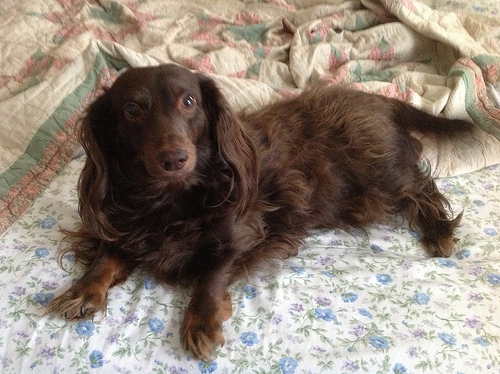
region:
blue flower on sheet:
[311, 304, 346, 324]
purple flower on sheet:
[313, 344, 324, 351]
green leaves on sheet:
[266, 335, 281, 351]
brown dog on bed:
[44, 41, 469, 330]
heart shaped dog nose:
[153, 147, 210, 176]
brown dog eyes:
[177, 85, 209, 123]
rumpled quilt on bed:
[281, 15, 458, 82]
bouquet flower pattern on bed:
[288, 291, 338, 338]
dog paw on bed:
[186, 335, 235, 365]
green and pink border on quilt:
[17, 134, 66, 172]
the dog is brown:
[58, 47, 453, 285]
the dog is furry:
[50, 43, 442, 339]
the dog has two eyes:
[66, 30, 307, 247]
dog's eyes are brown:
[109, 95, 217, 138]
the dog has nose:
[58, 50, 318, 279]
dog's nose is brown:
[146, 131, 208, 192]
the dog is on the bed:
[32, 12, 499, 370]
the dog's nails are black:
[59, 227, 299, 367]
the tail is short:
[343, 79, 495, 181]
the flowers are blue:
[311, 283, 428, 364]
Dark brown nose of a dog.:
[155, 144, 190, 173]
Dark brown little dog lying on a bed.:
[47, 63, 477, 365]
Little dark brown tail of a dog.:
[386, 95, 475, 136]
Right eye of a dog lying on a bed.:
[122, 99, 142, 121]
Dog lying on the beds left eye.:
[175, 91, 194, 112]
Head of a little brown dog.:
[107, 66, 207, 181]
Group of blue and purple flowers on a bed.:
[287, 289, 339, 336]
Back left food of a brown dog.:
[405, 165, 456, 257]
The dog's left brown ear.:
[191, 73, 259, 218]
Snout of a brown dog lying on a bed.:
[136, 121, 199, 180]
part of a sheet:
[329, 287, 402, 347]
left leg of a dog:
[186, 324, 226, 364]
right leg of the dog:
[66, 270, 126, 330]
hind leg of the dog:
[410, 209, 462, 268]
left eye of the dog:
[183, 99, 205, 111]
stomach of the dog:
[283, 144, 355, 197]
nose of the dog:
[166, 144, 198, 186]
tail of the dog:
[410, 107, 460, 138]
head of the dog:
[141, 60, 169, 120]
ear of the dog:
[207, 97, 262, 166]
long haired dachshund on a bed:
[61, 51, 434, 318]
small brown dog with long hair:
[40, 66, 459, 319]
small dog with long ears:
[57, 53, 440, 288]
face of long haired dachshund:
[74, 83, 230, 200]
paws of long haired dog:
[55, 243, 247, 372]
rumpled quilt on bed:
[125, 11, 459, 93]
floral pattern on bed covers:
[283, 299, 478, 371]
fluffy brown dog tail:
[321, 58, 485, 193]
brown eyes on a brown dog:
[111, 93, 216, 131]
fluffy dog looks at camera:
[48, 53, 391, 308]